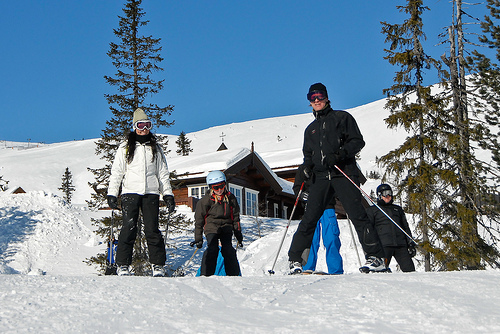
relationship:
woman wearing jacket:
[118, 138, 180, 194] [118, 147, 170, 192]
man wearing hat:
[305, 79, 334, 93] [310, 88, 323, 93]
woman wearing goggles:
[118, 138, 180, 194] [132, 118, 154, 131]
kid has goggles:
[213, 185, 234, 277] [132, 118, 154, 131]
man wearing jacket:
[305, 79, 334, 93] [118, 147, 170, 192]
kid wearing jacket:
[213, 185, 234, 277] [118, 147, 170, 192]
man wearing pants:
[305, 79, 334, 93] [302, 180, 378, 262]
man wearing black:
[305, 79, 334, 93] [314, 127, 347, 183]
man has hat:
[305, 79, 334, 93] [310, 88, 323, 93]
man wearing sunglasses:
[305, 79, 334, 93] [310, 93, 328, 106]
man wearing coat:
[305, 79, 334, 93] [302, 118, 356, 189]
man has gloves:
[305, 79, 334, 93] [323, 159, 344, 177]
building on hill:
[180, 144, 299, 224] [21, 147, 95, 217]